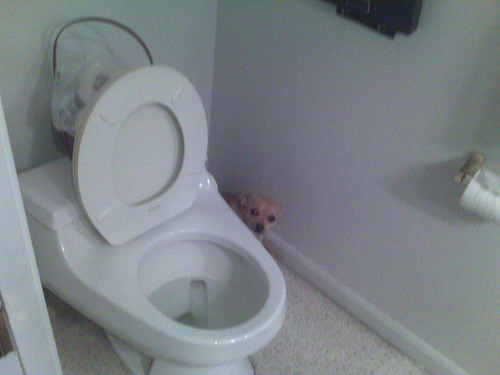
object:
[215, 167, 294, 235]
coat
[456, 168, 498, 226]
toilet tissue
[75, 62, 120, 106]
toilet tissue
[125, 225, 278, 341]
rim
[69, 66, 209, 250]
lid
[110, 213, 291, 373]
toilet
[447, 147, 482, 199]
holder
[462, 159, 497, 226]
toilet paper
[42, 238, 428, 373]
carpet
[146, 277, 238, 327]
water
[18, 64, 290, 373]
toilet bowl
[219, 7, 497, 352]
wall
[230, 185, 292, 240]
dog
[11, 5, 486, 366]
bathroom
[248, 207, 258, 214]
eye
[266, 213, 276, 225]
eye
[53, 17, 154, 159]
basket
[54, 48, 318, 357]
seat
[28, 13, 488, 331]
photo indoors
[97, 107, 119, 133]
stopper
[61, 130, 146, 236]
toilet seat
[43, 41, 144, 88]
toilet paper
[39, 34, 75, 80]
plastic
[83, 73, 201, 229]
bottom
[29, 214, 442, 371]
ground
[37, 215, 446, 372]
floor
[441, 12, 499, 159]
shadow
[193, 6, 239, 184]
corner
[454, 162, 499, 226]
roll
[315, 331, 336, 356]
patch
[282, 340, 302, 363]
patch